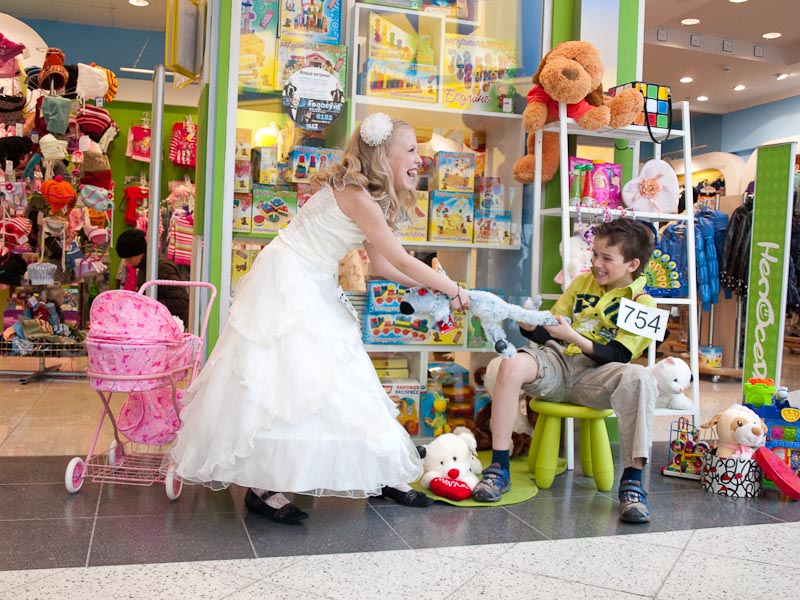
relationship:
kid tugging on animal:
[465, 205, 663, 516] [458, 263, 560, 353]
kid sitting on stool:
[465, 205, 663, 516] [520, 395, 621, 490]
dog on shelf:
[516, 40, 642, 186] [531, 105, 695, 229]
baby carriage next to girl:
[62, 270, 220, 502] [178, 112, 470, 525]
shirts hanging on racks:
[125, 121, 166, 168] [117, 54, 184, 294]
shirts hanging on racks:
[166, 117, 200, 175] [117, 54, 184, 294]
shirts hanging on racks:
[124, 178, 157, 226] [117, 54, 184, 294]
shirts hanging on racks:
[160, 180, 205, 271] [117, 54, 184, 294]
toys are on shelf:
[358, 11, 437, 104] [341, 4, 542, 256]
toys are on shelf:
[429, 138, 477, 192] [341, 4, 542, 256]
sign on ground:
[737, 140, 796, 393] [676, 387, 798, 491]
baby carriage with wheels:
[62, 270, 220, 502] [61, 444, 186, 497]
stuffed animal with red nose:
[413, 424, 482, 502] [442, 466, 460, 484]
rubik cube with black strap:
[615, 83, 667, 128] [641, 96, 677, 149]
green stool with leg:
[520, 389, 616, 490] [593, 421, 613, 493]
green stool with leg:
[520, 389, 616, 490] [577, 406, 598, 477]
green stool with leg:
[520, 389, 616, 490] [533, 415, 563, 493]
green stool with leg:
[520, 389, 616, 490] [520, 418, 540, 477]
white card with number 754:
[618, 296, 670, 342] [622, 303, 662, 335]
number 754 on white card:
[622, 303, 662, 335] [618, 296, 670, 342]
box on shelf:
[622, 157, 684, 216] [533, 102, 691, 219]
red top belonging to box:
[752, 440, 775, 501] [706, 451, 758, 496]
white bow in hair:
[359, 112, 393, 146] [295, 118, 408, 212]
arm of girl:
[368, 200, 477, 313] [178, 112, 470, 525]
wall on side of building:
[65, 3, 194, 270] [34, 2, 770, 596]